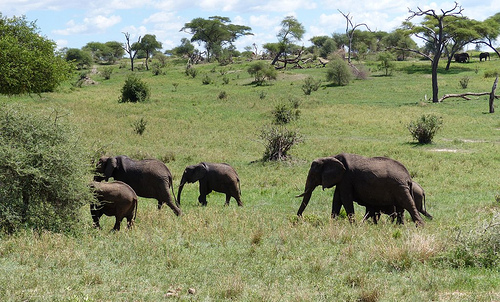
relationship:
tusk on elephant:
[296, 181, 320, 199] [297, 153, 422, 227]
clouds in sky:
[1, 1, 311, 13] [0, 0, 500, 50]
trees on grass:
[47, 16, 494, 73] [3, 59, 499, 300]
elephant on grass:
[297, 153, 422, 227] [3, 59, 499, 300]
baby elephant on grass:
[175, 163, 244, 205] [3, 59, 499, 300]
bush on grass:
[1, 105, 86, 239] [3, 59, 499, 300]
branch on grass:
[440, 91, 499, 104] [3, 59, 499, 300]